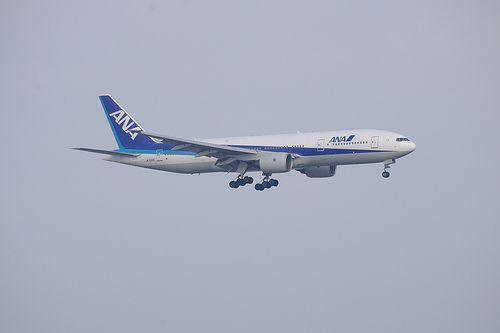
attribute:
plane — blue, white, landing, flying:
[68, 93, 418, 192]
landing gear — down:
[218, 170, 390, 191]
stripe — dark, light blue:
[154, 143, 398, 157]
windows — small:
[331, 140, 369, 147]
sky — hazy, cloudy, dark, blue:
[2, 1, 499, 92]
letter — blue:
[327, 135, 336, 143]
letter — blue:
[336, 135, 344, 144]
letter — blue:
[339, 134, 347, 144]